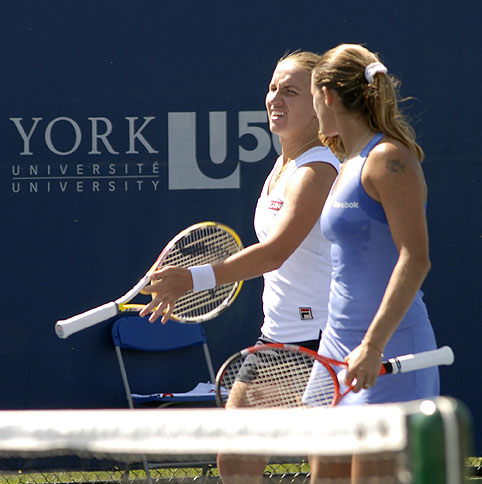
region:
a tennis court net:
[1, 396, 465, 482]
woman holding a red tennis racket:
[213, 342, 461, 408]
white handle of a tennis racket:
[388, 343, 454, 370]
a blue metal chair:
[111, 314, 232, 482]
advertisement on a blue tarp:
[5, 109, 284, 199]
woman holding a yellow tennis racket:
[52, 216, 245, 343]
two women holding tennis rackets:
[54, 45, 456, 480]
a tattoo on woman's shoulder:
[388, 158, 407, 180]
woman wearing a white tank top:
[253, 149, 344, 341]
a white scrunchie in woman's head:
[366, 57, 387, 83]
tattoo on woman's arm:
[372, 154, 416, 179]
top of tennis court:
[284, 398, 417, 460]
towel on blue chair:
[137, 372, 240, 415]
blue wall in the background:
[79, 21, 206, 82]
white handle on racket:
[388, 347, 462, 379]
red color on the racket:
[295, 341, 351, 392]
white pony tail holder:
[345, 52, 417, 111]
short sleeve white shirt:
[229, 140, 365, 237]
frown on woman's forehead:
[270, 69, 314, 91]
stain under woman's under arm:
[337, 188, 399, 233]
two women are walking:
[48, 41, 456, 481]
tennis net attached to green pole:
[0, 396, 479, 482]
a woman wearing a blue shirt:
[302, 32, 456, 337]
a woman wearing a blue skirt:
[296, 303, 446, 414]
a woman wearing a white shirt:
[241, 140, 345, 348]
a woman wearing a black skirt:
[233, 317, 325, 396]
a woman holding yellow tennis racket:
[46, 47, 346, 481]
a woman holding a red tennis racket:
[212, 40, 455, 479]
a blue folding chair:
[110, 307, 222, 482]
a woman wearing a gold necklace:
[265, 131, 331, 187]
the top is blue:
[324, 199, 441, 364]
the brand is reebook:
[314, 185, 378, 222]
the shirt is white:
[247, 174, 331, 330]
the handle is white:
[57, 301, 122, 349]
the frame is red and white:
[216, 333, 362, 407]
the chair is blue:
[112, 319, 214, 398]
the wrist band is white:
[182, 257, 221, 301]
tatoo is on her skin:
[384, 156, 412, 184]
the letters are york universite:
[21, 115, 190, 190]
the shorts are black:
[225, 343, 319, 393]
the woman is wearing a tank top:
[326, 139, 432, 338]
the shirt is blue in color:
[318, 133, 433, 331]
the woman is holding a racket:
[210, 336, 454, 422]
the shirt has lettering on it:
[328, 198, 361, 211]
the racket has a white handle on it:
[382, 347, 457, 380]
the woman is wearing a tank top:
[252, 144, 354, 345]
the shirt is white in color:
[252, 149, 354, 343]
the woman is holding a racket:
[55, 219, 245, 333]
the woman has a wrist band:
[187, 261, 215, 294]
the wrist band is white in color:
[190, 259, 218, 293]